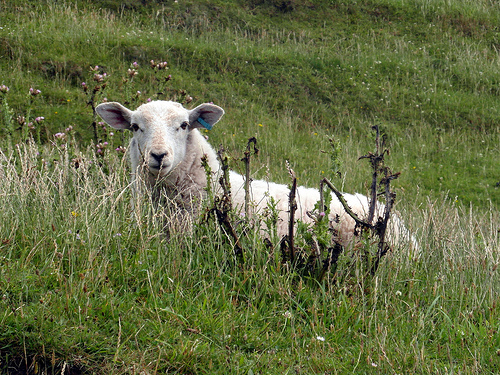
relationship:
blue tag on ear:
[196, 115, 214, 132] [189, 101, 227, 130]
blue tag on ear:
[196, 115, 214, 132] [93, 101, 131, 130]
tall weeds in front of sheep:
[15, 139, 495, 309] [84, 92, 423, 259]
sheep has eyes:
[84, 92, 423, 259] [179, 120, 190, 132]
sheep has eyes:
[84, 92, 423, 259] [130, 121, 144, 133]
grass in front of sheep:
[0, 130, 201, 303] [84, 92, 423, 259]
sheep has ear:
[84, 92, 423, 259] [92, 97, 127, 130]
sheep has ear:
[84, 92, 423, 259] [189, 91, 226, 132]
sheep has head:
[84, 92, 423, 259] [92, 83, 225, 191]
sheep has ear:
[84, 92, 423, 259] [89, 96, 134, 132]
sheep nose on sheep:
[146, 148, 171, 164] [84, 92, 423, 259]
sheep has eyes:
[84, 92, 423, 259] [128, 117, 191, 134]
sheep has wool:
[84, 92, 423, 259] [229, 175, 375, 218]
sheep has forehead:
[84, 92, 423, 259] [137, 105, 179, 122]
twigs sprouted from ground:
[326, 121, 401, 270] [1, 2, 498, 373]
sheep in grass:
[84, 92, 423, 259] [5, 119, 497, 373]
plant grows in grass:
[321, 121, 405, 299] [0, 202, 500, 373]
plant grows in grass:
[242, 134, 262, 249] [0, 202, 500, 373]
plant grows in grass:
[358, 121, 386, 257] [0, 202, 500, 373]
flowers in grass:
[75, 47, 181, 82] [2, 9, 492, 199]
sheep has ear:
[84, 92, 423, 259] [190, 103, 223, 131]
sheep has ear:
[84, 92, 423, 259] [93, 99, 131, 136]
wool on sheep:
[131, 101, 421, 252] [84, 92, 423, 259]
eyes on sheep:
[118, 121, 216, 145] [98, 93, 342, 294]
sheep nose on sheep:
[151, 148, 172, 164] [84, 92, 423, 259]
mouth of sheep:
[146, 158, 171, 171] [56, 65, 466, 310]